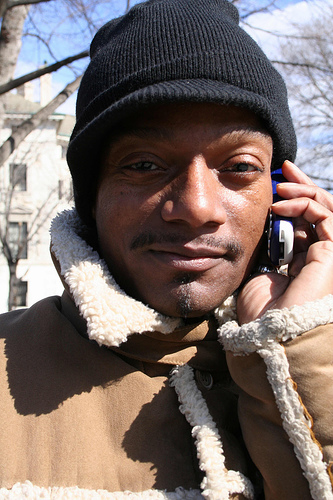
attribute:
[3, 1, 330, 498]
man — looking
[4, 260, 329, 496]
coat — brown, white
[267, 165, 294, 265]
phone — blue, white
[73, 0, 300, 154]
cap — black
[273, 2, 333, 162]
trees — leaveless, blurry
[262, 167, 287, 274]
cellphone — blue, white